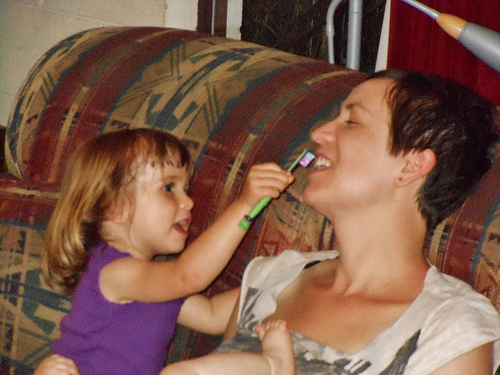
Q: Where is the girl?
A: On woman's lap.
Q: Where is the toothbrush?
A: In girl's hand.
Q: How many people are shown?
A: 2.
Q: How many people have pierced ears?
A: 1.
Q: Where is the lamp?
A: Background.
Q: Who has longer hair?
A: The girl.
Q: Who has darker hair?
A: The woman.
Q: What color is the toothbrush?
A: Green.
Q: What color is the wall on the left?
A: White.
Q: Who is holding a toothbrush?
A: The little girl.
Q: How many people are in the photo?
A: 2.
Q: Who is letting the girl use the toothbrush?
A: The woman.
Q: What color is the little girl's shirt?
A: Purple.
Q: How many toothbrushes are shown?
A: 1.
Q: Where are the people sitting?
A: On a sofa.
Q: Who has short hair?
A: The woman.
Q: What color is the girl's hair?
A: Light brown.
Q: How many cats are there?
A: None.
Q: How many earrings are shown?
A: One.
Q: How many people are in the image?
A: Two.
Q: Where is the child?
A: On the woman's lap.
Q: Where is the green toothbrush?
A: In the child's hand.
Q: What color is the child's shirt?
A: Purple.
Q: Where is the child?
A: On the woman's lap.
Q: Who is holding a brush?
A: The child.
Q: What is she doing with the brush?
A: Brushing the woman's teeth.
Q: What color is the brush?
A: Green.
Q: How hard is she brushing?
A: Softly.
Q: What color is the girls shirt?
A: Purple.